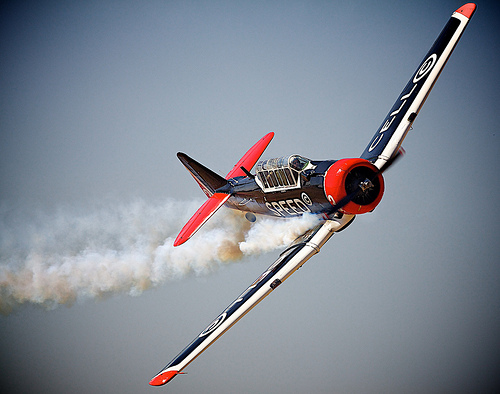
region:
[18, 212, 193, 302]
The plane has a huge line of smoke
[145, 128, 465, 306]
The plane is patriotic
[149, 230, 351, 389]
The wing of the plane is long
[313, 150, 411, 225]
The front of the plane has a propeller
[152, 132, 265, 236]
The tail of the plane is pointed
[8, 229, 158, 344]
The smoke is gray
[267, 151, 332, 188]
The pilot is driving the plane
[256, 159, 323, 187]
A window in the top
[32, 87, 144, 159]
The sky has no clouds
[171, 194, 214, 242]
The tail of the plane is red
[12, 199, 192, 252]
white smoke coming from the airplane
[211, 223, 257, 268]
brown smoke coming out of the plane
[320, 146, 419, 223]
black propellers on the plane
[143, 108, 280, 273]
red tail of the plane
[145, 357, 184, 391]
red tips of the wings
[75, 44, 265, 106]
dark gray sky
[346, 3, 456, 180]
white writing on the wing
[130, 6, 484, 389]
a red white and black airplane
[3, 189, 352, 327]
smoke billowing from the plane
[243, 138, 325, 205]
the cockpit of the plane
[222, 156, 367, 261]
A plane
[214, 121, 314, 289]
A plane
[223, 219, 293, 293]
A plane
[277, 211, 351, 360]
A plane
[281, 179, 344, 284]
A plane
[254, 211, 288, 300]
A plane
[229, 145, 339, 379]
A plane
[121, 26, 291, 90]
The sky is blue.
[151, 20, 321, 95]
The sky is clear.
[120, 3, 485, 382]
The plane is flying.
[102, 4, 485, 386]
The plane is red, white and black.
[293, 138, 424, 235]
The propeller is moving.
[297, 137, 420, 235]
The propeller has two blades.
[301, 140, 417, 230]
The propeller is black.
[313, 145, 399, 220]
The tip of the plane is red.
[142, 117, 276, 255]
The plane has red wings.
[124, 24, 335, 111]
The sky has no clouds in it.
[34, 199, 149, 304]
white smoke emitted from jet doing tricks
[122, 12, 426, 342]
jet performing tricks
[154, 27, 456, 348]
red white and black jet performing tricks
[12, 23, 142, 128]
light blue sky without clouds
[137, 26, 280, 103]
light blue sky without clouds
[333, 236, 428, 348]
light blue sky without clouds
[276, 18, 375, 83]
light blue sky without clouds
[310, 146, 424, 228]
propeller and red nose of jet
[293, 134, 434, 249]
propeller and red nose of airplane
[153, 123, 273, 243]
red and black tail of airplane